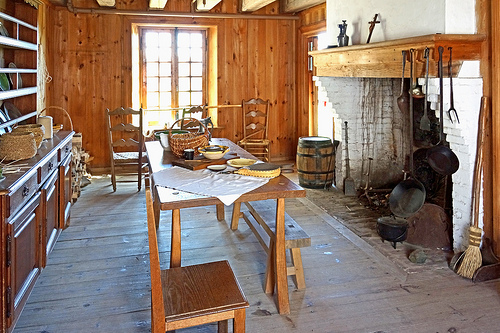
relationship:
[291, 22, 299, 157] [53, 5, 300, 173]
pole in wall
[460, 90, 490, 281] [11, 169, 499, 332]
broom rests on floor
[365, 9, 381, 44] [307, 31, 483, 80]
crucifix on mantle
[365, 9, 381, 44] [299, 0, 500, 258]
crucifix leans on wall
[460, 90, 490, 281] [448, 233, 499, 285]
broom in a dust pan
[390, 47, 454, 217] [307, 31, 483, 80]
cooking utensils hang from mantle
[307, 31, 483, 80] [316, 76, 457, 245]
mantle over fireplace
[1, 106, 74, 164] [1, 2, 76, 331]
baskets on china cabinet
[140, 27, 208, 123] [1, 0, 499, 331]
window in room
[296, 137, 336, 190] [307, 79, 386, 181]
barrel near white brick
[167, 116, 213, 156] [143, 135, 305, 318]
basket on table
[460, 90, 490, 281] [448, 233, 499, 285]
broom and dust pan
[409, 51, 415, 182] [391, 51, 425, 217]
long handle on a pan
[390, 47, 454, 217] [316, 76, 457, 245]
cooking utensils over fireplace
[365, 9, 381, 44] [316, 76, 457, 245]
crucifix over fireplace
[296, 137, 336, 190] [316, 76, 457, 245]
barrel next to fireplace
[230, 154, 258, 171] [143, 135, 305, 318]
dish on table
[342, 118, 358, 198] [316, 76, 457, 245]
shovel by fireplace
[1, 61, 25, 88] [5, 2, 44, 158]
plates on shelves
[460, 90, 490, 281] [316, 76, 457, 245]
broom next to fireplace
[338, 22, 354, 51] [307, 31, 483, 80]
sculpture on mantle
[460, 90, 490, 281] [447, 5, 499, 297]
broom in corner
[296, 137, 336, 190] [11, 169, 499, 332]
barrel on floor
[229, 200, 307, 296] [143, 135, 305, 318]
bench under table